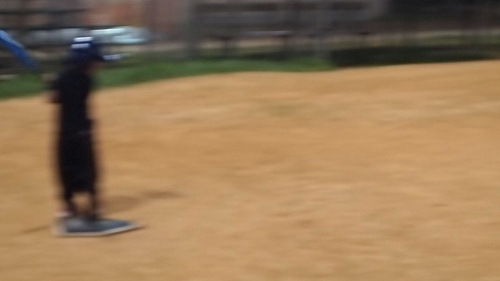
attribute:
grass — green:
[4, 55, 329, 95]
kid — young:
[44, 35, 101, 217]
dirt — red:
[307, 135, 410, 218]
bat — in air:
[6, 29, 40, 61]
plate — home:
[52, 199, 177, 247]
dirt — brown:
[3, 58, 498, 280]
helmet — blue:
[47, 22, 112, 67]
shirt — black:
[48, 58, 98, 133]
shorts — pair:
[52, 126, 105, 197]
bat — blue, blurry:
[2, 30, 55, 84]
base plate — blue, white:
[48, 207, 143, 248]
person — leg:
[41, 36, 107, 221]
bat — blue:
[0, 28, 51, 88]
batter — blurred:
[41, 35, 115, 225]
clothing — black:
[44, 60, 102, 203]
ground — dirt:
[244, 144, 369, 245]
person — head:
[59, 40, 109, 220]